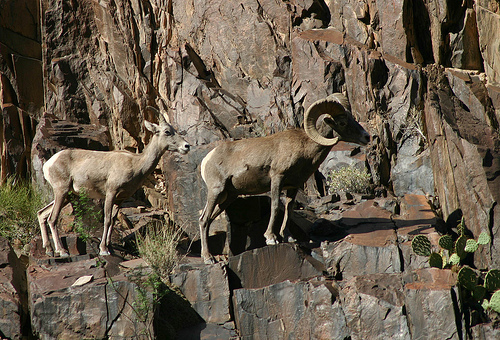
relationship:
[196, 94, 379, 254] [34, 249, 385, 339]
ram on rock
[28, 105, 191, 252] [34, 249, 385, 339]
ram on rock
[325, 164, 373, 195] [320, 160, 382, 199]
flowering weed on bush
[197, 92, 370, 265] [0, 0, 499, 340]
animal standing on cliff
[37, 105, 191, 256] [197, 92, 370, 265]
animals following animal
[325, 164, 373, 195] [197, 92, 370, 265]
flowering weed beside animal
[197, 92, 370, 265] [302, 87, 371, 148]
animal has head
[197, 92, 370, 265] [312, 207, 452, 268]
animal casting shadow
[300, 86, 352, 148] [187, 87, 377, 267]
curved horn on animal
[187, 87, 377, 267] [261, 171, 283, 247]
animal has leg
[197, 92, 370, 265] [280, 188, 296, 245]
animal has leg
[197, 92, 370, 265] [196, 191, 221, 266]
animal has leg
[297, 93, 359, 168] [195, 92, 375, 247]
horns on animal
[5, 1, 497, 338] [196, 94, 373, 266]
landscape used by ram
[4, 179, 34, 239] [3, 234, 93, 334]
bushes on rock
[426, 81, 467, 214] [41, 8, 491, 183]
crack on wall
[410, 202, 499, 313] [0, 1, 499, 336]
cacti growing on rockface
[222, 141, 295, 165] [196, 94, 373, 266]
brown fur on side of ram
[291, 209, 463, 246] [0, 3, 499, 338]
shadow on rocks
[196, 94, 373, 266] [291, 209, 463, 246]
ram has shadow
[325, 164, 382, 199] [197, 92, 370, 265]
flowering weed in front animal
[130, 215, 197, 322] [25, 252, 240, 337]
vegetation in rocks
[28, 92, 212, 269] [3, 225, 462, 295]
ram on ledge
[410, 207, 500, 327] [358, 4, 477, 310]
cacti on rock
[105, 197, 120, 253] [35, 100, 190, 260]
leg on ram